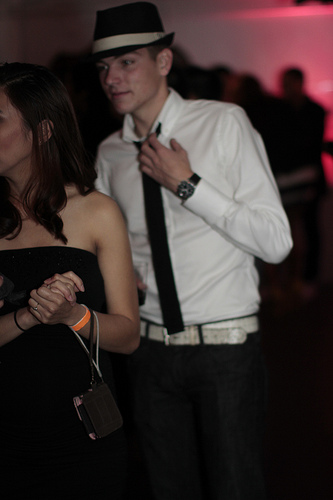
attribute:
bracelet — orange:
[69, 303, 92, 331]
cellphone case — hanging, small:
[71, 305, 124, 437]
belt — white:
[136, 315, 259, 345]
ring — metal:
[31, 302, 41, 313]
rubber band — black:
[13, 306, 28, 333]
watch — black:
[176, 174, 201, 202]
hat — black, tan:
[83, 2, 175, 62]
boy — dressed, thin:
[90, 0, 295, 498]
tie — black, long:
[132, 119, 184, 333]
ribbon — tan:
[90, 31, 169, 52]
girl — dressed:
[0, 61, 143, 495]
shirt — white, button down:
[91, 86, 292, 328]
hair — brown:
[0, 61, 97, 245]